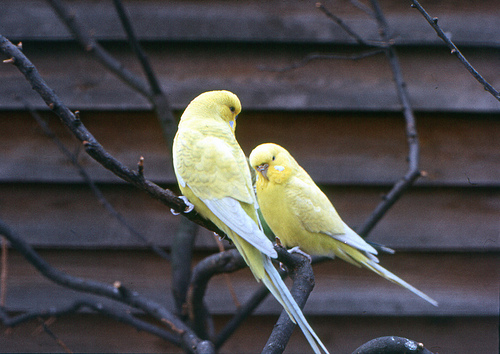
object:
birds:
[171, 89, 332, 354]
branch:
[1, 0, 499, 354]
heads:
[178, 89, 243, 128]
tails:
[221, 224, 331, 354]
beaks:
[256, 163, 270, 181]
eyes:
[272, 155, 276, 161]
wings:
[171, 130, 279, 258]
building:
[1, 1, 499, 353]